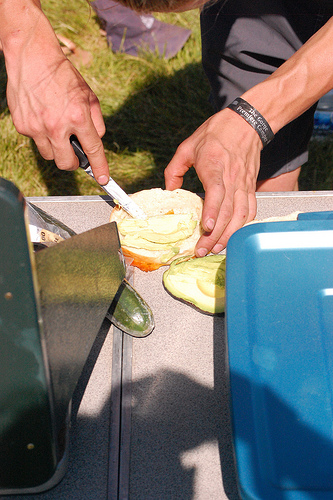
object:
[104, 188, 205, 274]
food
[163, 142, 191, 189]
thumb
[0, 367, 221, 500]
shadow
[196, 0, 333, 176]
shorts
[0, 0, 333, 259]
man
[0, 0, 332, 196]
grass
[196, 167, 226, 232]
finger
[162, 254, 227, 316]
avacado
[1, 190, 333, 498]
table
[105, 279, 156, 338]
cucumber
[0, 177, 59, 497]
lid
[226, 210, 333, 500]
lid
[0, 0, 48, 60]
wrist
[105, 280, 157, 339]
plastic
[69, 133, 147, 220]
knife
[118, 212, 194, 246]
slice